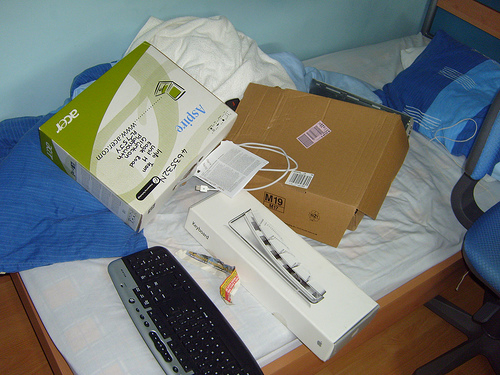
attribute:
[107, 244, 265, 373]
keyboard — black, silver, grey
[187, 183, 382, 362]
box — silver, white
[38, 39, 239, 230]
box — white, green, acer, acer aspire, grey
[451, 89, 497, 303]
chair — blue, black, comfortable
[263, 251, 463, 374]
bed — wood, tan, wooden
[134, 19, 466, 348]
sheets — white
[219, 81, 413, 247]
box — brown, cardboard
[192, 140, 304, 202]
cord — white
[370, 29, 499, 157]
pillow case — blue, dark blue, light blue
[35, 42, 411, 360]
boxes — open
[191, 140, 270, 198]
instructions — white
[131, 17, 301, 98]
blanket — white, crumpled, wrinkled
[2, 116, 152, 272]
comforter — blue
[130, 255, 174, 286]
keys — black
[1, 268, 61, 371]
counter — brown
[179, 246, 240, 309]
paper — crinkled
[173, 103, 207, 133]
words — blue, bold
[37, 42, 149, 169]
area — green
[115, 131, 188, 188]
writing — black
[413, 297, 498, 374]
base — black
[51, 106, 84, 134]
writing — white